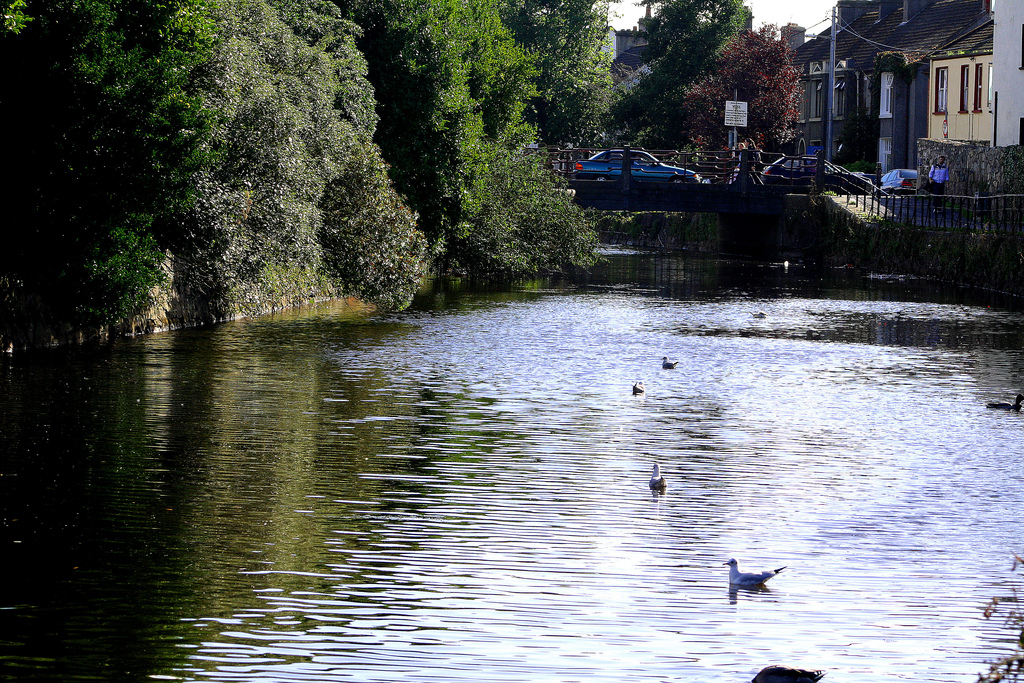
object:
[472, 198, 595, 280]
leaves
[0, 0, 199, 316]
leaves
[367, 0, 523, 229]
tree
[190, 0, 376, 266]
tree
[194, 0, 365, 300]
leaves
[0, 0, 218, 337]
tree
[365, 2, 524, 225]
leaves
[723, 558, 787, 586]
bird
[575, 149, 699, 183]
car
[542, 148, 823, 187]
fence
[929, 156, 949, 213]
man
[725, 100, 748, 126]
sign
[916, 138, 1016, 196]
wall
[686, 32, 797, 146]
tree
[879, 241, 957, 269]
moss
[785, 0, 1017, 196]
house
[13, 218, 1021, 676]
water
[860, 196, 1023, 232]
sidewalk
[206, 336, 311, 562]
reflection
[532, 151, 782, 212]
bridge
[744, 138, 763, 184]
person